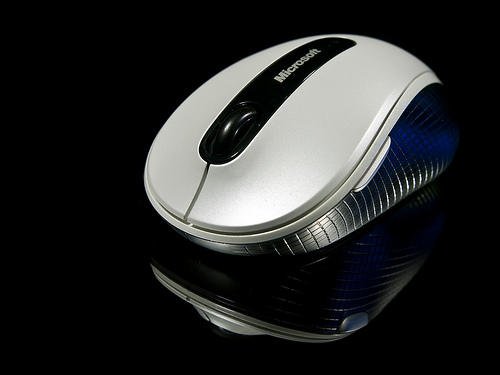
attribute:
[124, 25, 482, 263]
mouse — plastic, reflecting, black, white, round, curvy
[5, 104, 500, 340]
surface — black, shiny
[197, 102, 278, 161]
wheel — black